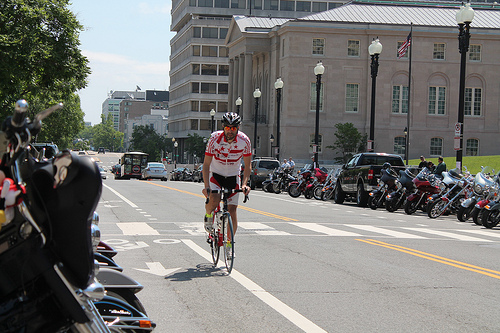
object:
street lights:
[252, 88, 262, 158]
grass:
[459, 156, 497, 169]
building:
[168, 0, 349, 163]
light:
[455, 0, 476, 171]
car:
[141, 162, 168, 181]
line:
[104, 178, 499, 333]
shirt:
[205, 130, 252, 177]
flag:
[398, 31, 412, 59]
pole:
[405, 22, 412, 167]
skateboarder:
[199, 105, 255, 277]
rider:
[202, 112, 252, 261]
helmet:
[221, 111, 243, 125]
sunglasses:
[223, 125, 238, 131]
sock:
[205, 213, 213, 218]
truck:
[335, 153, 437, 207]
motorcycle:
[481, 199, 499, 228]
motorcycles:
[428, 166, 476, 219]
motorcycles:
[457, 165, 499, 222]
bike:
[206, 186, 250, 273]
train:
[100, 52, 158, 73]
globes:
[269, 3, 476, 88]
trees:
[10, 1, 81, 170]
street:
[77, 150, 497, 331]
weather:
[79, 6, 185, 116]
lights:
[367, 36, 384, 153]